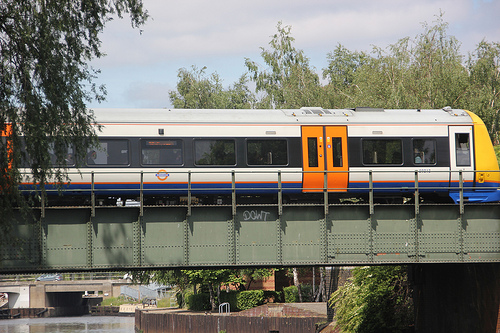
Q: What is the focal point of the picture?
A: Train.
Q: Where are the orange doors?
A: Side.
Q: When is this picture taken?
A: Daytime.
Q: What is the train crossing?
A: Bridge.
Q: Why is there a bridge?
A: Because of the water.